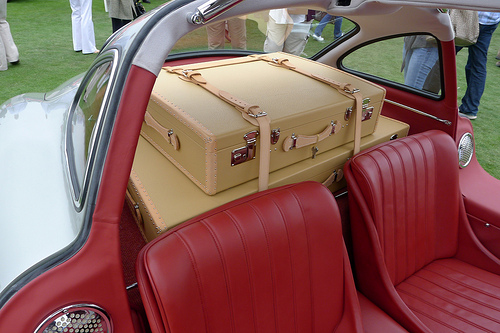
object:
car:
[1, 0, 493, 331]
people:
[396, 0, 477, 91]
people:
[444, 1, 500, 119]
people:
[262, 6, 313, 55]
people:
[308, 14, 346, 42]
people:
[67, 0, 99, 54]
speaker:
[31, 300, 113, 331]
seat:
[141, 180, 378, 332]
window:
[339, 34, 442, 98]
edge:
[336, 30, 445, 100]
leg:
[402, 42, 441, 93]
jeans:
[403, 46, 440, 88]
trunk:
[0, 0, 462, 293]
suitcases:
[120, 116, 410, 246]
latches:
[231, 131, 259, 167]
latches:
[361, 97, 374, 122]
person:
[458, 10, 499, 118]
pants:
[460, 20, 496, 116]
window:
[168, 5, 358, 58]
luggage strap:
[162, 66, 270, 191]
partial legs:
[229, 14, 247, 50]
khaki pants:
[206, 14, 247, 50]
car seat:
[341, 129, 498, 331]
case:
[133, 50, 388, 196]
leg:
[459, 14, 494, 118]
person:
[66, 0, 101, 55]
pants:
[69, 0, 94, 53]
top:
[53, 306, 103, 318]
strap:
[248, 52, 362, 153]